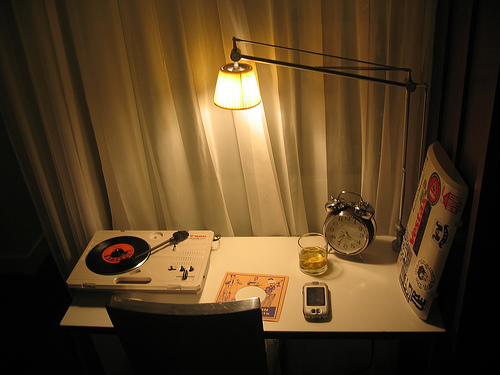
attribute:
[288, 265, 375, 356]
cellphone — silver, dark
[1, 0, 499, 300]
curtains — white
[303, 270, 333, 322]
phone — grey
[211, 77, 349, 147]
lamp — extending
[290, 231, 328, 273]
glass — clear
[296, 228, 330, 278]
glass — clear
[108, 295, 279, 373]
chair — black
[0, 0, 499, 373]
drapery — white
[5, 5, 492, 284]
wall — white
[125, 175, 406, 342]
chair — wooden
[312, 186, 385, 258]
clock — metal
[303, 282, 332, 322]
device — small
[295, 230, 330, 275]
cup — Glass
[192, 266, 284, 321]
record container — purple, orange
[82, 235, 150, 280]
record — black, orange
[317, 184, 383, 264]
alarm clock — old style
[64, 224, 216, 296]
record/turntable — flat, white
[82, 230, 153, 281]
record — black, vinyl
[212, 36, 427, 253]
desk lamp — on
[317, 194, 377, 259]
clock — silver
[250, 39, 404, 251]
pole — metal